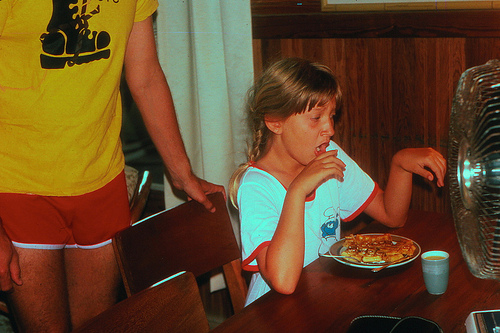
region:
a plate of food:
[324, 217, 439, 285]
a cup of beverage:
[410, 238, 457, 303]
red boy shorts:
[0, 132, 139, 248]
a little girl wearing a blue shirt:
[235, 35, 403, 329]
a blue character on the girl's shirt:
[312, 200, 352, 272]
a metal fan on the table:
[423, 45, 498, 280]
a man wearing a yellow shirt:
[0, 0, 200, 200]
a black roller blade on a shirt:
[13, 2, 154, 83]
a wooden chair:
[111, 172, 252, 330]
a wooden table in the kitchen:
[304, 285, 371, 331]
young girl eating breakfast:
[219, 48, 457, 301]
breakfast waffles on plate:
[332, 226, 422, 277]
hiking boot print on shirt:
[37, 1, 120, 70]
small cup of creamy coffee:
[419, 245, 451, 298]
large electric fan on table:
[445, 46, 497, 332]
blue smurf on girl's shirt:
[313, 198, 345, 257]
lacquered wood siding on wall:
[254, 26, 477, 238]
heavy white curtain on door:
[151, 1, 264, 298]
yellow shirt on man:
[2, 1, 157, 197]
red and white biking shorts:
[2, 181, 143, 261]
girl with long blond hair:
[227, 39, 386, 307]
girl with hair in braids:
[212, 66, 380, 212]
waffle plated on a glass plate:
[312, 215, 432, 289]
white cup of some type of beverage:
[417, 237, 463, 310]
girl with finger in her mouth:
[233, 51, 364, 281]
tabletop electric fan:
[446, 48, 498, 332]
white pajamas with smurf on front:
[310, 187, 368, 262]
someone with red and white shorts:
[0, 143, 142, 280]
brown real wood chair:
[100, 172, 259, 307]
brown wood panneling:
[202, 7, 467, 229]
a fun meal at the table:
[16, 3, 487, 309]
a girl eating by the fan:
[224, 39, 498, 307]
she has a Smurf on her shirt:
[306, 188, 365, 290]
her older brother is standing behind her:
[6, 7, 363, 309]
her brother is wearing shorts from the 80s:
[8, 78, 421, 324]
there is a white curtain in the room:
[157, 6, 349, 330]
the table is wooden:
[102, 180, 498, 331]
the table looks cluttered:
[350, 250, 495, 331]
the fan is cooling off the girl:
[233, 42, 498, 283]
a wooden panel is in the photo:
[258, 12, 473, 224]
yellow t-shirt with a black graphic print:
[3, 0, 171, 191]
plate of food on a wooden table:
[330, 225, 421, 275]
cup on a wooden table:
[420, 246, 450, 296]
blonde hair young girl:
[227, 52, 448, 292]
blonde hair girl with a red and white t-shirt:
[226, 55, 446, 305]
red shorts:
[1, 171, 131, 251]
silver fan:
[451, 56, 497, 287]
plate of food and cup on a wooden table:
[331, 229, 451, 309]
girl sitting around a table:
[226, 57, 424, 331]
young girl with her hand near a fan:
[216, 44, 498, 325]